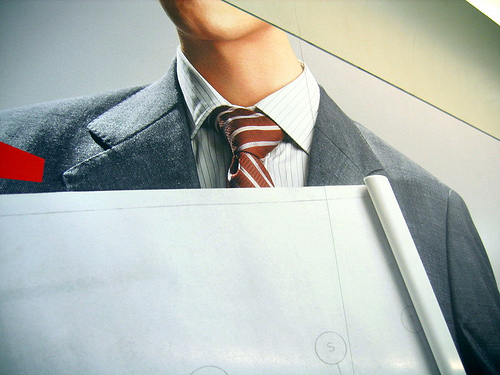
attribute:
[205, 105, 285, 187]
tie — red, white, brown, silver, striped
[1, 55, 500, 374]
suit — gray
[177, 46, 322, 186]
shirt — striped, white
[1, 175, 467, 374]
paper — white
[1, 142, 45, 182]
object — red